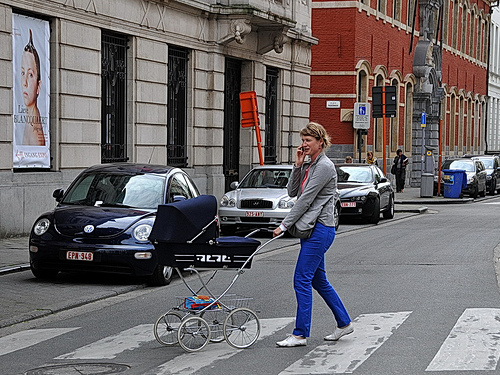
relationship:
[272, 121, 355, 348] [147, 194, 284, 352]
woman pushing stroller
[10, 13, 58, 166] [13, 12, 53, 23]
advertisment covering a window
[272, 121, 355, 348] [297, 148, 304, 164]
woman on phone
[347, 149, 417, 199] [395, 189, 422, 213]
people walking down sidewalk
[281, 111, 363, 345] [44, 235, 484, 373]
woman crosses street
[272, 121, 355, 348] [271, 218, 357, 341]
woman has pants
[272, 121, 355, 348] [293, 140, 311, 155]
woman on phone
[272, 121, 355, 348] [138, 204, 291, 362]
woman pushes a stroller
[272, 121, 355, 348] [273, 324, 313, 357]
woman wears shoe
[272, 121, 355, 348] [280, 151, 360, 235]
woman wears a sweater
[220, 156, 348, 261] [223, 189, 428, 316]
silver car on street